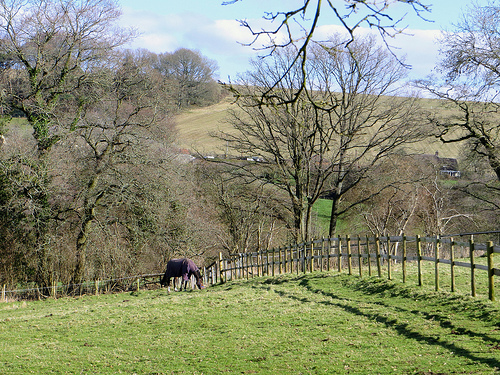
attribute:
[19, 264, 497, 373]
grass — green, short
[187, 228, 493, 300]
fence — brown, wooden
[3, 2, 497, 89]
sky — blue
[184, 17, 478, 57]
clouds — white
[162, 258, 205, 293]
horse — gray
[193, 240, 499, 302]
wooden fence — long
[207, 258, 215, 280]
slat — white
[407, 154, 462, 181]
house — white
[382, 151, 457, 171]
roof — brown